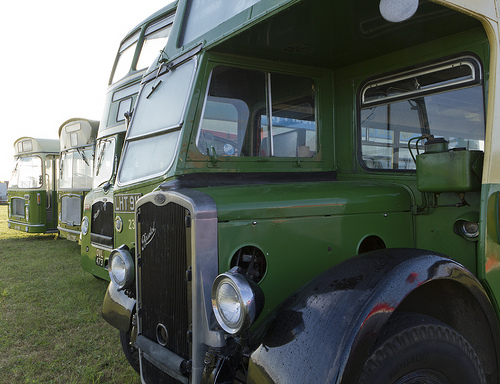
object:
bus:
[99, 0, 499, 383]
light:
[211, 266, 257, 334]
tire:
[354, 312, 488, 383]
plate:
[114, 194, 143, 211]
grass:
[0, 204, 141, 384]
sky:
[0, 0, 175, 180]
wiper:
[146, 61, 166, 99]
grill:
[136, 201, 190, 384]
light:
[107, 244, 133, 291]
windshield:
[126, 55, 197, 137]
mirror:
[379, 1, 419, 22]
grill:
[60, 195, 82, 226]